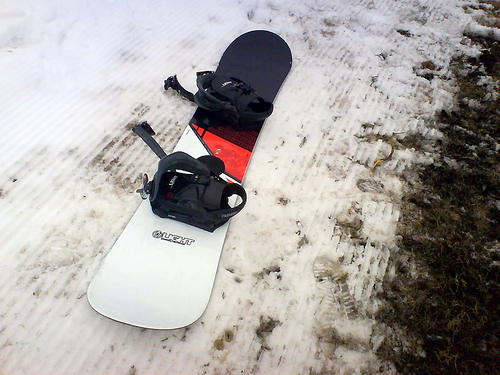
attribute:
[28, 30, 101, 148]
snow — lot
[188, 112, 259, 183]
middle — red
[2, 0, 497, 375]
snow — white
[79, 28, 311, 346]
snowboard — red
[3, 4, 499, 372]
outside — sunny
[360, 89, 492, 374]
grass — dark green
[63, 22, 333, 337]
snowboard — colorful 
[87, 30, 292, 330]
board — red, white, black, empty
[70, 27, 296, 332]
snowboard — empty, orange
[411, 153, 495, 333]
weeds — green